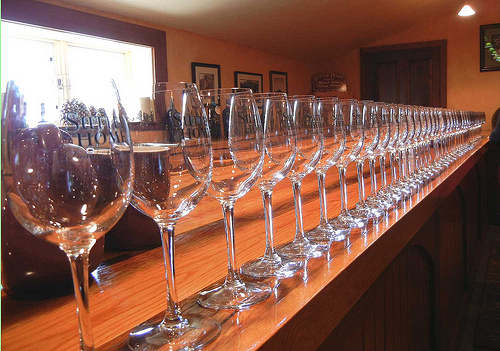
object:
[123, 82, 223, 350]
glass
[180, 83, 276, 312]
glass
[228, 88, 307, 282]
glass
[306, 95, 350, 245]
glass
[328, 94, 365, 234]
glass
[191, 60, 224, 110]
print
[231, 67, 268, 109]
print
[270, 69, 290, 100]
print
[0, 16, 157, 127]
window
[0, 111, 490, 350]
counter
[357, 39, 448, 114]
door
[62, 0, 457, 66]
ceiling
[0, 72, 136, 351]
glasses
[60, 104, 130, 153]
words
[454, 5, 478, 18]
light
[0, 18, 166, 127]
sunlight